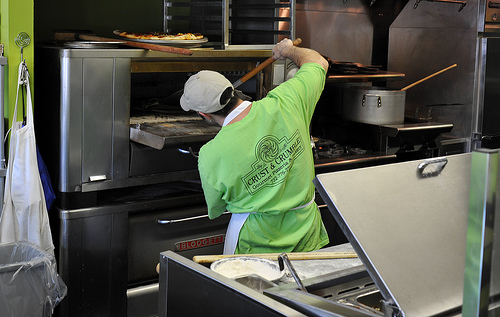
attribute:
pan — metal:
[113, 30, 209, 48]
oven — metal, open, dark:
[36, 40, 301, 316]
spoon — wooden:
[399, 63, 458, 92]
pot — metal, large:
[344, 86, 404, 125]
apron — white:
[0, 61, 58, 270]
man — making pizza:
[179, 38, 332, 256]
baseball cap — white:
[179, 69, 235, 113]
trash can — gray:
[0, 240, 53, 316]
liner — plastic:
[0, 239, 68, 315]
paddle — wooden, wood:
[233, 37, 304, 102]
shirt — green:
[198, 63, 330, 256]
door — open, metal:
[130, 122, 225, 152]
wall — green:
[1, 1, 35, 168]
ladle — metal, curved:
[278, 254, 309, 295]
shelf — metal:
[317, 115, 454, 155]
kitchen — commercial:
[1, 1, 500, 316]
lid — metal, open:
[311, 151, 500, 315]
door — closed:
[127, 202, 234, 289]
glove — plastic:
[271, 37, 294, 58]